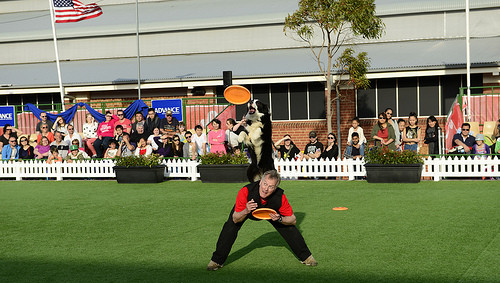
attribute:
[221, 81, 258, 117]
frisbee — orange, airborne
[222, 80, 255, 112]
frisbee — orange, round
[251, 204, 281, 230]
frisbee — round, orange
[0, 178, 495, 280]
astroturf — green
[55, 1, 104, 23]
american flag — waving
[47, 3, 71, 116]
flag pole — white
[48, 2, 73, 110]
flag pole — white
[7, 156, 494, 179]
picket fence — white, long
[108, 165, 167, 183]
planter — large, black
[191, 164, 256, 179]
planter — black, large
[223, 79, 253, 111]
frisbee — orange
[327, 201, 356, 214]
frisbee — orange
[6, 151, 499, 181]
fence — short, white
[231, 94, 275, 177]
dog — white, black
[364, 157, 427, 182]
flower pot — black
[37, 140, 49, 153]
shirt — purple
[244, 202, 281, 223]
frisbee — orange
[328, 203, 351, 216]
frisbee — orange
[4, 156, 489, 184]
fence — picket , white , short 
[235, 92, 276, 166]
dog — white , black 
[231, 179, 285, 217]
shirt — red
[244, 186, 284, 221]
vest — black 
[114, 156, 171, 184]
plants — green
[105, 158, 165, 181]
planter — black 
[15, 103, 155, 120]
ribbon — blue , cloth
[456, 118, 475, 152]
man — one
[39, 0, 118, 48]
flag — red, white, blue